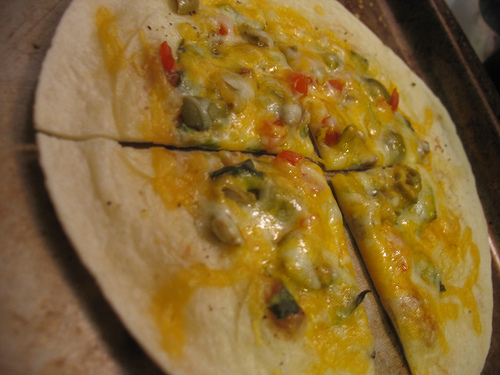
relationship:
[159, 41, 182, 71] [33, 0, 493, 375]
pepper on cheese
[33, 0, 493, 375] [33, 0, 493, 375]
cheese cut in cheese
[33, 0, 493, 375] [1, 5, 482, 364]
cheese on a table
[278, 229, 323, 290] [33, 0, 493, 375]
meat ball on a cheese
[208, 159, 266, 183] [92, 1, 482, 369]
cilantro in cheese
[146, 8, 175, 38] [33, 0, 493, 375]
spots on cheese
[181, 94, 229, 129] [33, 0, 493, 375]
meat ball on top of baked cheese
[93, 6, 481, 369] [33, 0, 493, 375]
glaze on top of baked cheese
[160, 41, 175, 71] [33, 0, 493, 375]
pepper on top of baked cheese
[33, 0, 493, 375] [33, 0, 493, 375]
cheese in cheese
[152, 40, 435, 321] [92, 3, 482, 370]
vegetables into sauce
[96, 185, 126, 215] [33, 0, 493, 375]
fleck on cheese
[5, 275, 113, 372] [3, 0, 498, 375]
marks on grill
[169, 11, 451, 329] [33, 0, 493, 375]
cheese on cheese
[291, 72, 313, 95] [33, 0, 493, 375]
red pepper are on cheese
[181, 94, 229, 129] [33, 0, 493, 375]
meat ball are on cheese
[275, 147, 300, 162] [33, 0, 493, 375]
peppers are on cheese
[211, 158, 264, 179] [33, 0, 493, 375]
cilantro are on cheese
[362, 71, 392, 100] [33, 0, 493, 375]
peppers are on cheese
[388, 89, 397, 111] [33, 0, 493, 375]
peppers are on cheese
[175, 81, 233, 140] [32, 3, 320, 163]
meat ball on pizza